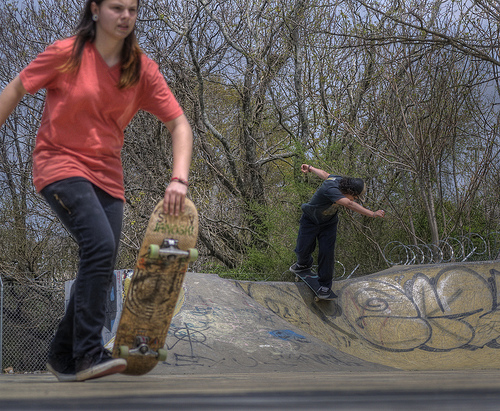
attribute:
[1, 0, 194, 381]
girl — skateboarding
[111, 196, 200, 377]
skateboard — graffitied, brown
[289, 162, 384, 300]
man — skateboarding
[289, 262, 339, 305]
skateboard — black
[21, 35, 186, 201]
shirt — orange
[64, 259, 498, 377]
wall — graffitied, concrete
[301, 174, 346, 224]
shirt — black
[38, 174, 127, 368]
pants — black, dark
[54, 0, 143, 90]
hair — long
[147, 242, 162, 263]
wheel — green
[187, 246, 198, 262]
wheel — green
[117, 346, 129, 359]
wheel — green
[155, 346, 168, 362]
wheel — green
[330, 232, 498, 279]
wire — barbed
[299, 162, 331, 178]
arm — raised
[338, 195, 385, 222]
arm — raised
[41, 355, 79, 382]
shoe — black, white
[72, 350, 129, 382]
shoe — black, white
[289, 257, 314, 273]
shoe — black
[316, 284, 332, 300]
shoe — black